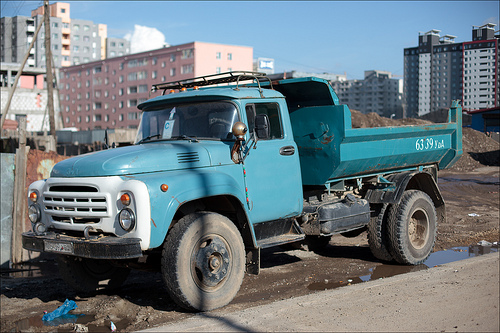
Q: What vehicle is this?
A: Dump truck.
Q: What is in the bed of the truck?
A: Dirt.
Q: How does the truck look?
A: Light blue.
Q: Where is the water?
A: Near the truck's tires.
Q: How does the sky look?
A: Clear.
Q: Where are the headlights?
A: On the front of the truck.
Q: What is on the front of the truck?
A: The headlights.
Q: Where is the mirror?
A: On the driver's side of the truck.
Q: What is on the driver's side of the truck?
A: A mirror.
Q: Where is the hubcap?
A: On the tire.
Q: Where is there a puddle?
A: By the rear tire.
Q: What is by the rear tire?
A: A puddle.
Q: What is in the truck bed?
A: Dirt.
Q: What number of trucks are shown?
A: One.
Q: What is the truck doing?
A: Parked.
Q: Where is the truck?
A: In dirt.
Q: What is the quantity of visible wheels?
A: Two.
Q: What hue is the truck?
A: Light blue.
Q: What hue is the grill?
A: White.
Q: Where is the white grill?
A: On the front of truck.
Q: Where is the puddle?
A: Under truck.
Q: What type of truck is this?
A: Dump truck.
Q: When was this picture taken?
A: Daytime.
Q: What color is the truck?
A: Blue.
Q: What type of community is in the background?
A: City.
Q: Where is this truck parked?
A: Side of road.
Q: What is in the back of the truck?
A: Dirt.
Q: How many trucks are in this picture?
A: 1.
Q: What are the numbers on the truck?
A: 6339.